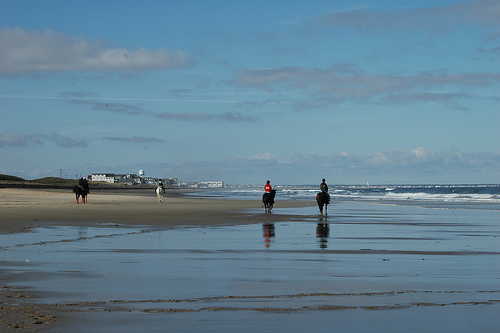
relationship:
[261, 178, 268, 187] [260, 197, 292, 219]
rider with horse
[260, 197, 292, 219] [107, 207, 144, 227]
horse on sand